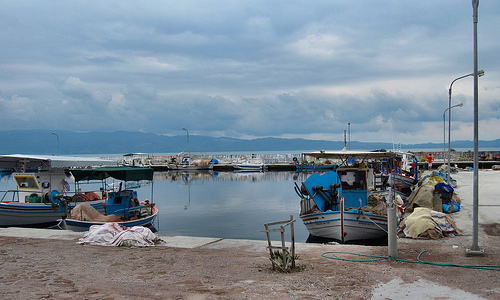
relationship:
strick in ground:
[254, 217, 308, 281] [273, 253, 371, 293]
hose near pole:
[321, 249, 500, 272] [442, 9, 492, 256]